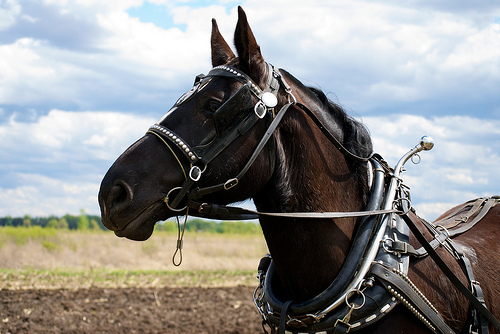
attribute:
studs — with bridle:
[150, 122, 195, 160]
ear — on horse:
[208, 5, 264, 65]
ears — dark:
[197, 7, 261, 69]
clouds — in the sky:
[309, 6, 496, 92]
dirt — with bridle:
[1, 284, 326, 332]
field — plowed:
[3, 237, 254, 282]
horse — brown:
[84, 40, 492, 315]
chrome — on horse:
[387, 133, 435, 173]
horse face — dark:
[96, 73, 274, 240]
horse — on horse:
[44, 12, 484, 312]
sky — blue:
[0, 0, 498, 220]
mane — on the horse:
[314, 83, 378, 162]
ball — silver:
[421, 134, 433, 149]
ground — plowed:
[8, 278, 282, 330]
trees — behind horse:
[3, 210, 251, 230]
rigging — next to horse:
[266, 133, 481, 333]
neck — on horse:
[259, 73, 368, 246]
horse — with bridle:
[95, 2, 499, 332]